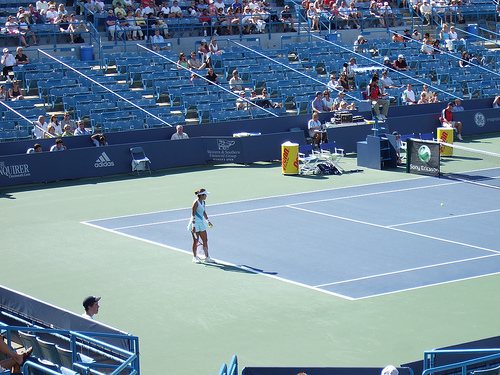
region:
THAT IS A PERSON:
[190, 188, 213, 248]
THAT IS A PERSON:
[81, 293, 102, 323]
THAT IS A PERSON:
[54, 135, 69, 160]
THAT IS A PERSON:
[23, 140, 44, 159]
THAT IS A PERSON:
[160, 126, 200, 151]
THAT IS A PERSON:
[295, 107, 342, 152]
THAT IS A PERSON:
[439, 101, 456, 131]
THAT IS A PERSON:
[226, 60, 243, 95]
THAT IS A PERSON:
[187, 37, 196, 85]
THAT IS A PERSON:
[186, 39, 206, 73]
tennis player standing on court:
[186, 187, 217, 269]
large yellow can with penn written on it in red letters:
[278, 140, 300, 175]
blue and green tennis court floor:
[5, 135, 499, 372]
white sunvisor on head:
[194, 186, 211, 200]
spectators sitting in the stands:
[3, 43, 108, 159]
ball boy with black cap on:
[78, 292, 103, 317]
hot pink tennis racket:
[188, 226, 210, 265]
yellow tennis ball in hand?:
[205, 220, 212, 228]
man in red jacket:
[435, 100, 465, 142]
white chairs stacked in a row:
[295, 143, 347, 179]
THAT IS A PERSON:
[187, 173, 211, 275]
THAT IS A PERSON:
[305, 114, 328, 139]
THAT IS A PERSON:
[162, 124, 202, 139]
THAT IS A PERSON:
[91, 124, 115, 135]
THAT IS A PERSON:
[83, 118, 123, 155]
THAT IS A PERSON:
[44, 133, 64, 158]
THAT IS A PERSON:
[48, 124, 57, 137]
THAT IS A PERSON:
[31, 118, 46, 128]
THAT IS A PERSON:
[172, 43, 187, 73]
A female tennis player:
[180, 181, 221, 271]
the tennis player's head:
[192, 187, 210, 202]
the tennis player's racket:
[190, 230, 209, 262]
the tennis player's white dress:
[187, 198, 209, 233]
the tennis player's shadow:
[199, 249, 280, 283]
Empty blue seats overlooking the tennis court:
[23, 34, 263, 133]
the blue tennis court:
[70, 164, 497, 302]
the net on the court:
[403, 131, 498, 184]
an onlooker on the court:
[79, 291, 104, 317]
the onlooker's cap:
[81, 291, 101, 311]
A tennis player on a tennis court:
[184, 183, 219, 267]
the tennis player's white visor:
[195, 190, 210, 199]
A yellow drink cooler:
[278, 139, 301, 177]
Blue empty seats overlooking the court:
[25, 50, 255, 131]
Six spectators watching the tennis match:
[29, 111, 97, 138]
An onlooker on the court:
[77, 291, 107, 319]